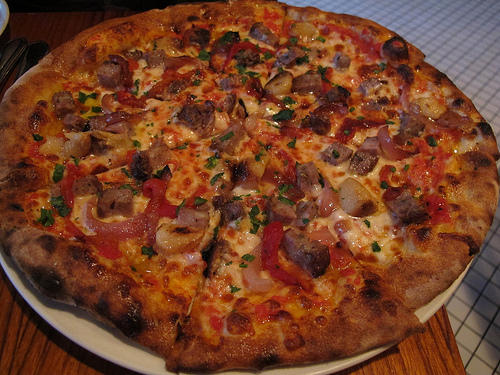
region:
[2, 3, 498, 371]
pizza on white plate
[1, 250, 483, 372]
white ceramic plate on wooden table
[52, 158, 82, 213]
red tomato on pizza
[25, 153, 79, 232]
green seasoning on top of pizza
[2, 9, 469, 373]
wooden table holding pizza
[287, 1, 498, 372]
black and white tiles on floor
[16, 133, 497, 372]
brown crust of pizza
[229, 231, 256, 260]
whtie cheese on pizza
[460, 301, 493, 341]
square shaped tiles on pizza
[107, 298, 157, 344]
burn mark on pizza crust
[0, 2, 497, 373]
Large pizza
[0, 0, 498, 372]
Large pizza on a white plate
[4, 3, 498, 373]
Large pizza on white plate sitting on a table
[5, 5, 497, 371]
Large pizza with multiple toppings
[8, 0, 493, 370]
Large pizza with meat and vegetable toppings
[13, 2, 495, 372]
Large pizza with meat, tomatoes, and onions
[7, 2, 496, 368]
Pizza with sausage and vegetables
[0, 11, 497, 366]
Large, cooked, delicious pizza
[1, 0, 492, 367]
Fresh pizza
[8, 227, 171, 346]
Burnt crust on pizza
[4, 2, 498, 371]
Yummy looking pizza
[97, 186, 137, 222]
Small brown piece of sausage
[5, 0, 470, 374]
Small brown table to hold food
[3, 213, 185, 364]
Brown and black burnt crust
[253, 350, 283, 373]
Small burnt part of crust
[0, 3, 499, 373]
Pizza sitting on white plate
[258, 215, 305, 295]
Small piece of sauce showing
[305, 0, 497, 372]
White tile floor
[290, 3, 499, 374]
Black grout in between white tiles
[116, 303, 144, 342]
Badly burnt part of crust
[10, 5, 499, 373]
one round multi-topping pizza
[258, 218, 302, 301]
sliver of red pepper on pizza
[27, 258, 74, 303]
burned section of pizza crust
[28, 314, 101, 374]
curved edge of white plate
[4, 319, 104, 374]
white plate on wooden table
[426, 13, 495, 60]
section of square shaped white tiles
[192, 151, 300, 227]
sprinkled green oregano on pizza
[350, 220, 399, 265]
cheese topping on pizza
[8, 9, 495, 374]
one large round pizza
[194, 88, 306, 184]
center section of cut round pizza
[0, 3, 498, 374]
a pizza on a plate.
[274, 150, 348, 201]
a piece of meat on a pizza.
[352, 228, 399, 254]
melted cheese on a pizza.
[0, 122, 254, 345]
A large slice of pizza.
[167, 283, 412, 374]
crust on a pizza.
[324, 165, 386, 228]
vegetable on a pizza.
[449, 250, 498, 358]
A section of a tiled floor.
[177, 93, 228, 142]
a piece of sausage.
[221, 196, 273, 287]
melted white cheese.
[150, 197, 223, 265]
a slice of mushroom.